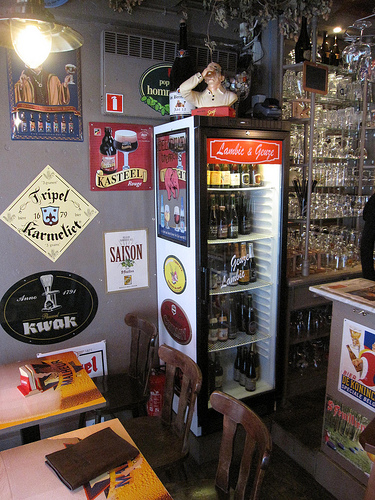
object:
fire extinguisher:
[146, 363, 167, 420]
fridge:
[151, 113, 292, 438]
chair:
[78, 308, 161, 429]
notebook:
[45, 426, 138, 493]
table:
[0, 415, 171, 498]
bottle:
[244, 295, 259, 335]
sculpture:
[177, 59, 240, 116]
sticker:
[105, 93, 124, 114]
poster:
[88, 123, 154, 191]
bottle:
[167, 18, 198, 122]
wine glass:
[332, 234, 343, 270]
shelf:
[288, 218, 366, 291]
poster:
[152, 127, 191, 250]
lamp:
[0, 3, 85, 72]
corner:
[1, 2, 106, 170]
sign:
[0, 266, 105, 348]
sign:
[103, 226, 150, 297]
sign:
[0, 165, 101, 266]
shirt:
[179, 73, 235, 107]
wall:
[0, 6, 277, 402]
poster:
[5, 40, 86, 143]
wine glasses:
[307, 229, 320, 273]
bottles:
[218, 192, 229, 240]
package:
[17, 362, 42, 398]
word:
[109, 244, 116, 263]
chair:
[161, 386, 275, 499]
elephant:
[164, 166, 180, 201]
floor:
[9, 394, 372, 499]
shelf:
[209, 294, 268, 356]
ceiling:
[3, 3, 374, 74]